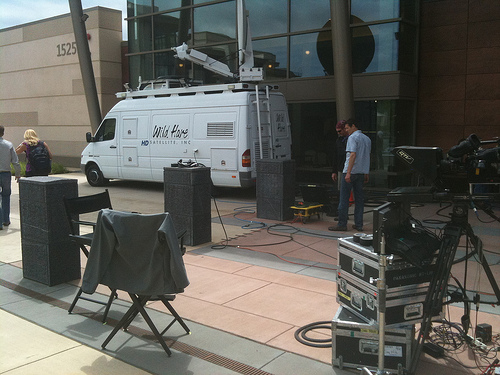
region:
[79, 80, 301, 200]
a white satellite truck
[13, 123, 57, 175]
a woman with blonde hair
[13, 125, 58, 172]
a woman wearing a bookbag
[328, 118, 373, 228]
two men looking down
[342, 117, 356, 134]
the head of a man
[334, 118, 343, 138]
the head of a man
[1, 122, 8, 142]
the head of a man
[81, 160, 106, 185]
the front wheel of a van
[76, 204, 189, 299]
a gray coat on the back of a chair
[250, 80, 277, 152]
the ladder on the back of a van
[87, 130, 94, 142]
The side mirror on the van.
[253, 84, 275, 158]
The ladder on the back of the van.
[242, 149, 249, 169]
The back brake light of the van.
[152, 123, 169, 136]
The word Wild on the side of the van.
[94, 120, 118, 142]
The window on the van's door.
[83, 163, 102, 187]
The front tire of the van.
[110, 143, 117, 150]
The door handle on the van.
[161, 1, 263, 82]
The antennae on the van's roof.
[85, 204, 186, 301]
The gray coat hanging on the chair.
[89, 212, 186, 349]
The chair the jacket is hanging on.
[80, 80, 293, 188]
A large white van that says Wild Hare on it.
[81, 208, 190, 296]
A long sleeve grey jacket on the back of a black chair.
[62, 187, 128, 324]
A black directors chair beside the one with a coat on it.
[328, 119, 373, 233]
Two men standing together talking, one in a blue shirt.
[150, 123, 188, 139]
Wild Hare in cursive writing.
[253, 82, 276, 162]
White ladder on the back of a white van.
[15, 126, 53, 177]
A blonde woman walking away with a black pack on.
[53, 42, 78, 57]
The number 1525 on a building.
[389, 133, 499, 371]
A large black camera on a black tripod.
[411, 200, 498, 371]
A black tripod under a large camera.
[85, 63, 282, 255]
the truck is white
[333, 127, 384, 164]
his shirt is white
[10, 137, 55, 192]
her bag is black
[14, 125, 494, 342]
This is a movie set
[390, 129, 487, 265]
high tec camera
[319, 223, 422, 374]
Many different electrical boxes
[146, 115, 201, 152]
the text says wild home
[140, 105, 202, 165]
the text is black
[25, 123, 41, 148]
her hair is blonde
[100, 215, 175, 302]
the coat is grey